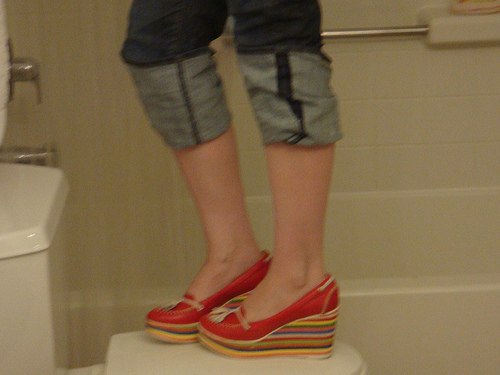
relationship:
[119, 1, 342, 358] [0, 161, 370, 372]
person standing on toilet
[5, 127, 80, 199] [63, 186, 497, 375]
faucet for bathtub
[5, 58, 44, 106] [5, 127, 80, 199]
handle of faucet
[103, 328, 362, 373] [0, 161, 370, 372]
lid of toilet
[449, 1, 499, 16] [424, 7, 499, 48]
soap resting in soap dish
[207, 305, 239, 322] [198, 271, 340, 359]
cording on top of shoe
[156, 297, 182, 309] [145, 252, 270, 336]
cording on top of shoe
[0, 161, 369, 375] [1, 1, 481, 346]
toilet in bathroom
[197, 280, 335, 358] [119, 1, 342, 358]
shoe on person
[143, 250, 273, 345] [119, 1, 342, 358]
shoe on person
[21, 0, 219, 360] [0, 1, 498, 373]
curtain in bathroom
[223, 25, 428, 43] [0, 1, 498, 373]
bar in bathroom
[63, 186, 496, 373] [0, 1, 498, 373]
bathtub in bathroom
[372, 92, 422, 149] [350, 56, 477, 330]
tile on wall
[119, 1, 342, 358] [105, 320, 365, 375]
person standing on seat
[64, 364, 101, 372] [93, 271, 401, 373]
hose between seat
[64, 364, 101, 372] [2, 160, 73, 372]
hose between cistern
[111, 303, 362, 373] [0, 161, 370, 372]
seat on toilet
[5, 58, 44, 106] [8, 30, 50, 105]
handle in bathtub